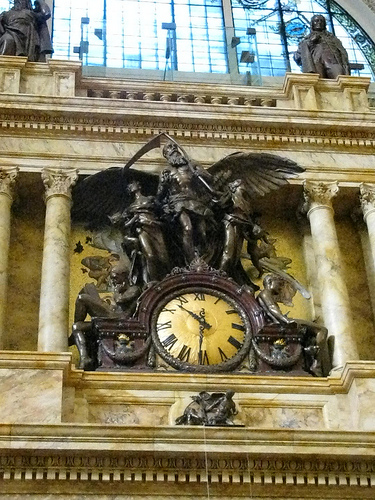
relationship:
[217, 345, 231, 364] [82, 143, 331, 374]
roman numeral on clock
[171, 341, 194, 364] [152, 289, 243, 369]
roman numeral on a clock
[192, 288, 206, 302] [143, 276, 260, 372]
numeral on clock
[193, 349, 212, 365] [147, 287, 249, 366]
numeral on clock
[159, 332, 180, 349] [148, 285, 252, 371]
numeral on clock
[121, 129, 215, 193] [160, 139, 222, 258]
scythe in hands of statue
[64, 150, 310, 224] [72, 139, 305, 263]
wings on back of statue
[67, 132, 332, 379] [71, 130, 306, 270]
sculptures of a angel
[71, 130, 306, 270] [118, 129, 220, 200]
angel with a tool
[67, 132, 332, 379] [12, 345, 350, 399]
sculptures on a ledge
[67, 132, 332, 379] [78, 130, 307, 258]
sculptures of an angel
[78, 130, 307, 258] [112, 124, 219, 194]
angel with a scythe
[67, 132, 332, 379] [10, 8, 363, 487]
sculptures in a cathedral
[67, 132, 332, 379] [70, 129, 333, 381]
sculptures and structures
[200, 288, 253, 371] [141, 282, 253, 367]
section of a clock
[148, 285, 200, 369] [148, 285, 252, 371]
section of a clock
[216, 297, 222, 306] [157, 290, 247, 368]
numeral on clock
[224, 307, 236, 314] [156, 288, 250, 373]
numeral on clock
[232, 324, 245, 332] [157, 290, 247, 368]
numeral on clock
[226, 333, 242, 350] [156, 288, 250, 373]
numeral on clock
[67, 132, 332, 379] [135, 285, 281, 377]
sculptures behind clock